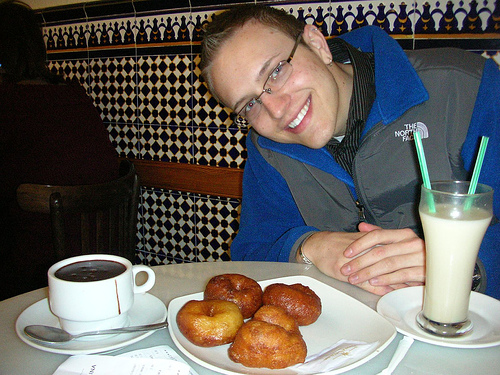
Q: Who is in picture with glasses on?
A: A man.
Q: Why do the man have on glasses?
A: To see.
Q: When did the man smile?
A: For the camera.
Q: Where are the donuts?
A: On a plate.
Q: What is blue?
A: A jacket.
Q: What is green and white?
A: Two straws.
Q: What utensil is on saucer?
A: A spoon.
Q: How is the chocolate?
A: In cup.